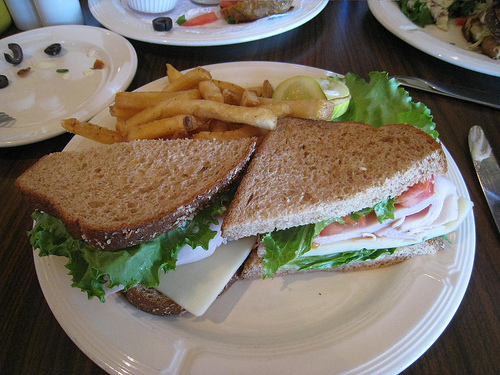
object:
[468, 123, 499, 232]
knife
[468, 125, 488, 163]
butter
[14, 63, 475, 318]
food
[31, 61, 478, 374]
plate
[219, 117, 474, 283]
sandwich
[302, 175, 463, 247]
meat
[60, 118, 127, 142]
french fry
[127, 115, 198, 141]
french fry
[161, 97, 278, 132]
french fry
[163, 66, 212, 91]
french fry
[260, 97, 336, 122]
french fry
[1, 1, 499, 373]
table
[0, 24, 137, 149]
plate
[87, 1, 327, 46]
plate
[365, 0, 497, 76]
plate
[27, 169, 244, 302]
lettuce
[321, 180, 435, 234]
tomato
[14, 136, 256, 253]
bread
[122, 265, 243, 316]
bread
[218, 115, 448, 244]
bread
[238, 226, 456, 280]
bread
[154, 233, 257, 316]
cheese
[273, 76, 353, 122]
pickle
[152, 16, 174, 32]
olive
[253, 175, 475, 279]
inside